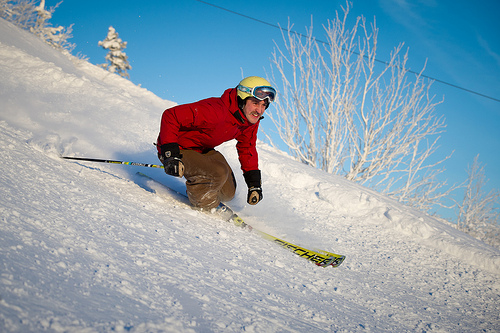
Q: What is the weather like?
A: It is cloudless.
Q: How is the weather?
A: It is cloudless.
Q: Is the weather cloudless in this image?
A: Yes, it is cloudless.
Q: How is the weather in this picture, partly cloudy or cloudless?
A: It is cloudless.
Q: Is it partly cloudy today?
A: No, it is cloudless.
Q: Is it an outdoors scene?
A: Yes, it is outdoors.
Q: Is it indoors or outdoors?
A: It is outdoors.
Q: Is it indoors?
A: No, it is outdoors.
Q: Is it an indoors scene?
A: No, it is outdoors.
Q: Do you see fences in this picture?
A: No, there are no fences.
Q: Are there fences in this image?
A: No, there are no fences.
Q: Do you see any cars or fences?
A: No, there are no fences or cars.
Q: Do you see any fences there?
A: No, there are no fences.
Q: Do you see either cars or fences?
A: No, there are no fences or cars.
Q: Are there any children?
A: No, there are no children.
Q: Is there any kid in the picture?
A: No, there are no children.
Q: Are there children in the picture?
A: No, there are no children.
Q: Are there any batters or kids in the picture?
A: No, there are no kids or batters.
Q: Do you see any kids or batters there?
A: No, there are no kids or batters.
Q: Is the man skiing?
A: Yes, the man is skiing.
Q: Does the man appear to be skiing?
A: Yes, the man is skiing.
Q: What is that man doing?
A: The man is skiing.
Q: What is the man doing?
A: The man is skiing.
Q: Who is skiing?
A: The man is skiing.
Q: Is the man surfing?
A: No, the man is skiing.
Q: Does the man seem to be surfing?
A: No, the man is skiing.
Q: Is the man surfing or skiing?
A: The man is skiing.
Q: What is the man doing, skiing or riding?
A: The man is skiing.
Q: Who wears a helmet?
A: The man wears a helmet.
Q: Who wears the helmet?
A: The man wears a helmet.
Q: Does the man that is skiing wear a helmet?
A: Yes, the man wears a helmet.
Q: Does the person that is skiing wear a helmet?
A: Yes, the man wears a helmet.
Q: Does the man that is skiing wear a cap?
A: No, the man wears a helmet.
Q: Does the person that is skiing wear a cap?
A: No, the man wears a helmet.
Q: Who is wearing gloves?
A: The man is wearing gloves.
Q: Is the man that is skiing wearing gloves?
A: Yes, the man is wearing gloves.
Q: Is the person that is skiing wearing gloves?
A: Yes, the man is wearing gloves.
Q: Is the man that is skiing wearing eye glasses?
A: No, the man is wearing gloves.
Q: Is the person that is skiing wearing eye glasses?
A: No, the man is wearing gloves.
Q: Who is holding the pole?
A: The man is holding the pole.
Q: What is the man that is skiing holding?
A: The man is holding the pole.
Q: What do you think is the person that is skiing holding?
A: The man is holding the pole.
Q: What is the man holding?
A: The man is holding the pole.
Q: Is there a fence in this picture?
A: No, there are no fences.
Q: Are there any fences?
A: No, there are no fences.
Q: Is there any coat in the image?
A: Yes, there is a coat.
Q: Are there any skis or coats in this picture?
A: Yes, there is a coat.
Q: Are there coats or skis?
A: Yes, there is a coat.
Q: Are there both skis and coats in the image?
A: Yes, there are both a coat and skis.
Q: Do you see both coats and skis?
A: Yes, there are both a coat and skis.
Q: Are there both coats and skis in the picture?
A: Yes, there are both a coat and skis.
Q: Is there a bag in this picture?
A: No, there are no bags.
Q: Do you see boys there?
A: No, there are no boys.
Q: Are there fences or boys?
A: No, there are no boys or fences.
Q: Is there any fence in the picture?
A: No, there are no fences.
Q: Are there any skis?
A: Yes, there are skis.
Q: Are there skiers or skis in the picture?
A: Yes, there are skis.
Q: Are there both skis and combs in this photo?
A: No, there are skis but no combs.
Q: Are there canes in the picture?
A: No, there are no canes.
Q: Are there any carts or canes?
A: No, there are no canes or carts.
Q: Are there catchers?
A: No, there are no catchers.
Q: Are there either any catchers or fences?
A: No, there are no catchers or fences.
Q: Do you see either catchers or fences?
A: No, there are no catchers or fences.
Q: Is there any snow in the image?
A: Yes, there is snow.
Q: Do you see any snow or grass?
A: Yes, there is snow.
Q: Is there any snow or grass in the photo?
A: Yes, there is snow.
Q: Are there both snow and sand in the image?
A: No, there is snow but no sand.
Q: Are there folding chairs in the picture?
A: No, there are no folding chairs.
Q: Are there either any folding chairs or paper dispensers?
A: No, there are no folding chairs or paper dispensers.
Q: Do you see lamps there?
A: No, there are no lamps.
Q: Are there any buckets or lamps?
A: No, there are no lamps or buckets.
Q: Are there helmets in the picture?
A: Yes, there is a helmet.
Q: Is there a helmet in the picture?
A: Yes, there is a helmet.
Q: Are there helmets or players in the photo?
A: Yes, there is a helmet.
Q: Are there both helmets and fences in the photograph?
A: No, there is a helmet but no fences.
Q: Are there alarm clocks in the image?
A: No, there are no alarm clocks.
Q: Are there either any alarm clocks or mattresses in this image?
A: No, there are no alarm clocks or mattresses.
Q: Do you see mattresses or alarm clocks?
A: No, there are no alarm clocks or mattresses.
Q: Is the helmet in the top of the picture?
A: Yes, the helmet is in the top of the image.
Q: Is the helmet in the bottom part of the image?
A: No, the helmet is in the top of the image.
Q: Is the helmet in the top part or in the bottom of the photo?
A: The helmet is in the top of the image.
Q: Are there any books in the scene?
A: No, there are no books.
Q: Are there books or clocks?
A: No, there are no books or clocks.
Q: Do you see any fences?
A: No, there are no fences.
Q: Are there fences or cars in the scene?
A: No, there are no fences or cars.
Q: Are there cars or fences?
A: No, there are no fences or cars.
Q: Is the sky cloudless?
A: Yes, the sky is cloudless.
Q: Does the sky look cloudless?
A: Yes, the sky is cloudless.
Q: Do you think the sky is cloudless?
A: Yes, the sky is cloudless.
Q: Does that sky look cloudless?
A: Yes, the sky is cloudless.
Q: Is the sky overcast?
A: No, the sky is cloudless.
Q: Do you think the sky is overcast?
A: No, the sky is cloudless.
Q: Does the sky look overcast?
A: No, the sky is cloudless.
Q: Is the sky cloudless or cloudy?
A: The sky is cloudless.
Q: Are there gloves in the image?
A: Yes, there are gloves.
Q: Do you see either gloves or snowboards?
A: Yes, there are gloves.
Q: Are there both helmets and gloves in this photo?
A: Yes, there are both gloves and a helmet.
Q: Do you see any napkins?
A: No, there are no napkins.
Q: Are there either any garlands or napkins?
A: No, there are no napkins or garlands.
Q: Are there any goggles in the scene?
A: Yes, there are goggles.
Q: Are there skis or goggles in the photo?
A: Yes, there are goggles.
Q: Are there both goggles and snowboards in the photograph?
A: No, there are goggles but no snowboards.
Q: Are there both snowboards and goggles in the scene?
A: No, there are goggles but no snowboards.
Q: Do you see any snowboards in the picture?
A: No, there are no snowboards.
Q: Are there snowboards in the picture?
A: No, there are no snowboards.